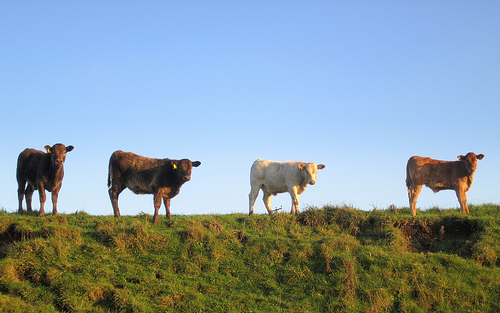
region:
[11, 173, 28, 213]
leg of large cow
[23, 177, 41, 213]
leg of large cow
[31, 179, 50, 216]
leg of large cow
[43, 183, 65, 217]
leg of large cow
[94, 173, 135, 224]
leg of large cow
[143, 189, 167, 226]
leg of large cow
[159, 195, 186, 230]
leg of large cow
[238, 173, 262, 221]
leg of large cow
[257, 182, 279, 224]
leg of large cow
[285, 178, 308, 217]
leg of large cow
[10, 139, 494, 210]
cows standing on the top of a hill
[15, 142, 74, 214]
a cow standing on the top of a hill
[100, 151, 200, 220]
a cow standing on the top of a hill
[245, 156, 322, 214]
a cow standing on the top of a hill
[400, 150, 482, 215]
a cow standing on the top of a hill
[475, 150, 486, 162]
the ear of a cow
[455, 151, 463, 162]
the ear of a cow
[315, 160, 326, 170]
the ear of a cow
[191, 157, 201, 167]
the ear of a cow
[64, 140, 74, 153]
the ear of a cow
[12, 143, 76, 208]
that is a calf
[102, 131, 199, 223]
that is a calf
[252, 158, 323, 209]
that is a calf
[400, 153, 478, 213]
that is a calf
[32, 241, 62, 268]
there is green grass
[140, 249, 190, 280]
there is green grass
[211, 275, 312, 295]
there is green grass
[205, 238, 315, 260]
there is green grass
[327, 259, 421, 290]
there is green grass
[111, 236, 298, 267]
there is green grass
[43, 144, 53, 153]
brown colored cow ear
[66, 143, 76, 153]
brown colored cow ear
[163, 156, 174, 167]
brown colored cow ear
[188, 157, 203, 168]
brown colored cow ear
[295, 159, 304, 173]
brown colored cow ear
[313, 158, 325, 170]
brown colored cow ear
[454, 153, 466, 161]
brown colored cow ear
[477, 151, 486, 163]
brown colored cow ear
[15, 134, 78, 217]
brown colored cow in field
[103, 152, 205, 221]
brown colored cow in field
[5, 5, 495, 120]
the blue sky behind the cows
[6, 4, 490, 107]
a cloudless blue sky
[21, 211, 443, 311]
green grass under the cows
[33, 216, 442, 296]
a hill with grass on it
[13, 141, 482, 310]
four cows standing on a hill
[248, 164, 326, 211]
a white cow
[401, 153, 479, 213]
a brown cow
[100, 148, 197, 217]
a dark brown cow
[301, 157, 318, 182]
the face of the white cow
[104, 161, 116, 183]
the tail of the cow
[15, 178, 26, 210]
leg of adult cow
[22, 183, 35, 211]
leg of adult cow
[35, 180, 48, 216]
leg of adult cow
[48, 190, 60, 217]
leg of adult cow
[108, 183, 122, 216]
leg of adult cow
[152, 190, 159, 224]
leg of adult cow